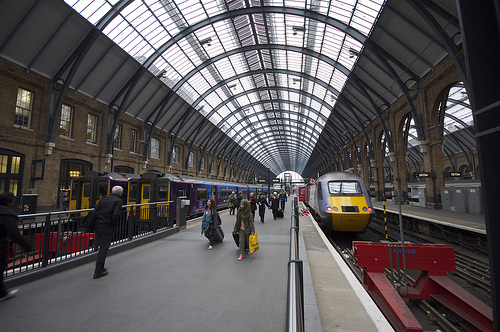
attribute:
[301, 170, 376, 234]
train — yellow, commuter, silver, subway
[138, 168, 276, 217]
train — blue, purple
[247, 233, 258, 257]
bag — yellow, shopping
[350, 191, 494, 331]
barrier — red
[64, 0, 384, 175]
ceiling — domed, glass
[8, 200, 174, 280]
fence — metal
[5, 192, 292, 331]
platform — grey, subway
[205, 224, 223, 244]
suitcase — pulled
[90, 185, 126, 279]
man — walking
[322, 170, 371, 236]
front — yellow, grey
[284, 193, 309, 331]
railing — metal, protective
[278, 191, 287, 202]
jacket — blue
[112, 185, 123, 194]
hair — white